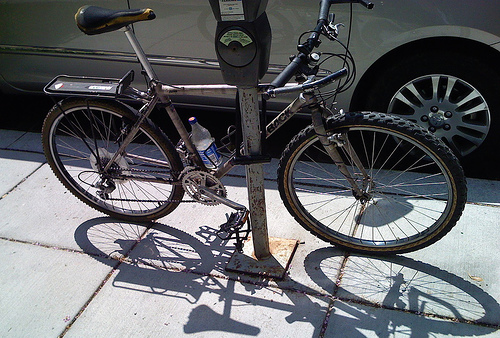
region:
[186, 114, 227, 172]
a plastic water bottle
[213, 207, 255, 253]
a black bicycle pedal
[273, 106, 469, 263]
a bicycle wheel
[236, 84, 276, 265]
a gray parking meter pole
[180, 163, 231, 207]
the gear of a bicycle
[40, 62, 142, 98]
the rack of a bicycle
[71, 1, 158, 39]
the black seat of a bicycle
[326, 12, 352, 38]
the handle brake of a bicycle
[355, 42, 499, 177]
the wheel of a car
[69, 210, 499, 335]
a shadow on the sidewalk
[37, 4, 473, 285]
The bicycle is secured to a parking meter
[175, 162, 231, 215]
This is the bike's sprocket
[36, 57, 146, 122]
A rear rack to carry things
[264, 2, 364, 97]
These are the bike's handle bars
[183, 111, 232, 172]
A drink holder with a bottle of water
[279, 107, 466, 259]
Front wheel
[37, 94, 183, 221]
Rear wheel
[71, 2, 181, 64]
The bike's seat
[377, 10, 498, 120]
A motor vehicle is parked here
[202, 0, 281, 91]
A parking meter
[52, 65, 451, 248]
this is a bicycle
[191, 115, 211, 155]
this is a bottle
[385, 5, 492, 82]
this is a vehicle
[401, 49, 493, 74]
this is a wheel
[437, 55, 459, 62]
the wheel is black in color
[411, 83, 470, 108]
this is the ream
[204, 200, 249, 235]
this is the pedal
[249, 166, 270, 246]
this is a pole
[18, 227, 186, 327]
this is the ground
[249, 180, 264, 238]
the pole is metallic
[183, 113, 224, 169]
a bottle of water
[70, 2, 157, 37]
a black bicycle seat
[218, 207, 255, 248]
a bicycle pedal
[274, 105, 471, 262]
the wheel of a bicycle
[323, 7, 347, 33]
the brake handle of a bicycle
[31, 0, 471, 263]
a bicycle on the sidewalk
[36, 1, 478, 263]
Bike is parking on street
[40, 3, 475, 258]
Bike is leaning on parking meter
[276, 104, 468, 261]
Front wheel of bike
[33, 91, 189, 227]
Back wheel of bike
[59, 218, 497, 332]
Shadow of bike on sidewalk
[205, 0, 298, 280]
PArking meter on street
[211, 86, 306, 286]
Pole of parking meter is rusty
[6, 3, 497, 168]
White car parking on side street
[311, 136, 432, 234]
Spokes of wheels are metal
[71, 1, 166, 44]
Sit of bike is high